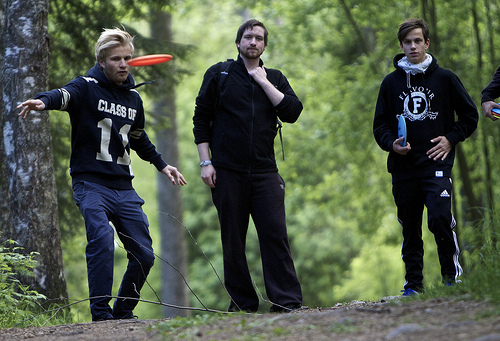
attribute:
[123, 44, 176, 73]
frisbe — airborn, orange, flying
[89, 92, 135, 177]
shirt — navy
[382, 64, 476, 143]
hoodie — blue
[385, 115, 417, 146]
frisbee — blue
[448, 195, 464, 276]
stripe — white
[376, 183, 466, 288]
pants — adidas, long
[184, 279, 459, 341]
hill — sandy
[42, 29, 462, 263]
players — playing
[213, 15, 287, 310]
man — standing, young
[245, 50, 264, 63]
hair — facial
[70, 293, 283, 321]
branch — small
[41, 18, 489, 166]
background — green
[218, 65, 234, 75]
logo — adidas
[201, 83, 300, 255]
outfit — black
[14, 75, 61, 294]
trunk — tall, strong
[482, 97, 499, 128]
frisbees — different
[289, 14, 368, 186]
tree — green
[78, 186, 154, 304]
jeans — blue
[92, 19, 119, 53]
hair — blond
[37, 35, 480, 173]
men — young, playing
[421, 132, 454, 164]
hand — resting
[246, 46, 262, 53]
mouth — closed